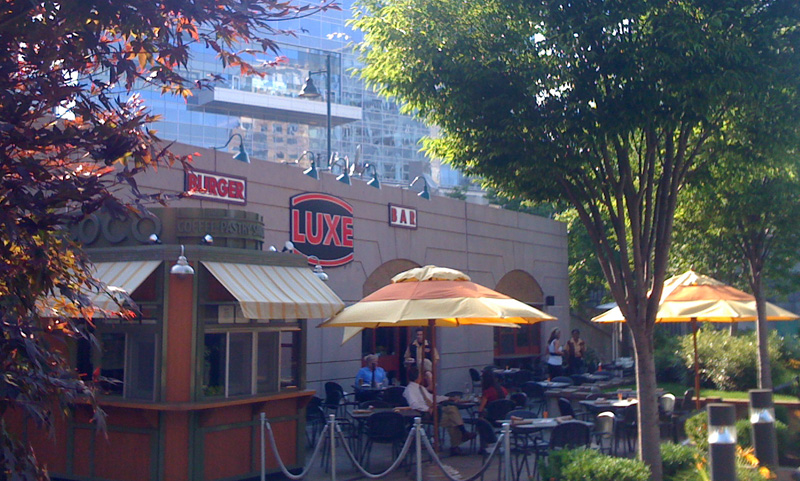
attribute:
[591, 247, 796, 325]
umbrella — orange, white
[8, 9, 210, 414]
leaves — red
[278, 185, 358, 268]
restaurant logo — named "Luxe"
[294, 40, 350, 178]
light pole — tall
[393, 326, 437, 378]
waiter — man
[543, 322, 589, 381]
people — appear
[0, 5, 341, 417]
red leaves — reddish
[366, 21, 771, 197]
part — top part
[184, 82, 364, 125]
platform — window washing